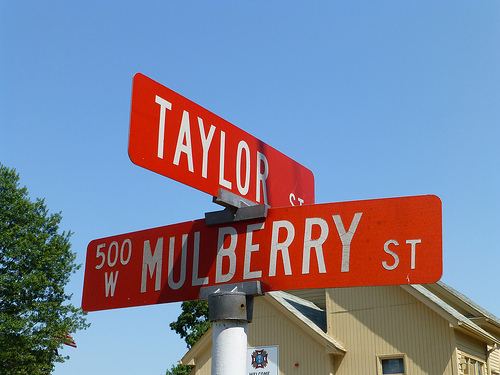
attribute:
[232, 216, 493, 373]
building — yellow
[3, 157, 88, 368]
tree — green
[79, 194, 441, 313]
sign — street , Mulberry St., red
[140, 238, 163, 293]
letter m — white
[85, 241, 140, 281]
number 500 — 500 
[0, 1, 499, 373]
sky — blue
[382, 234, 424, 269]
abbreviation — street 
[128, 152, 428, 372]
pole — white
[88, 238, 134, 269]
number 500 — 500 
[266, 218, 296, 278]
letter — R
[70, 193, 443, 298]
sign — street 